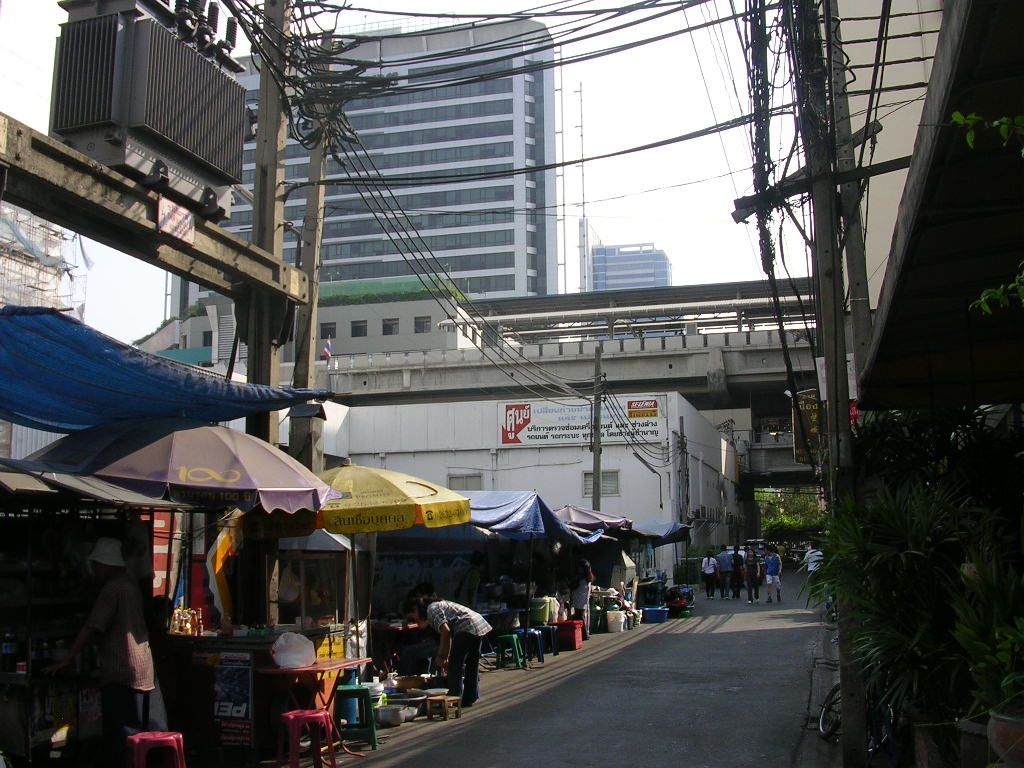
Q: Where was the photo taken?
A: At the marketplace.